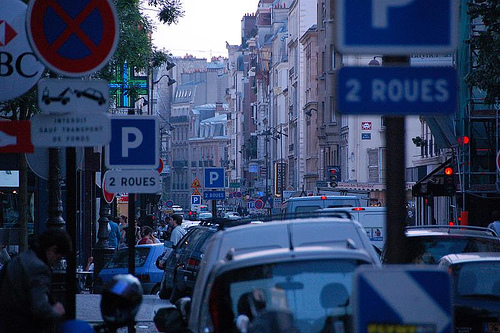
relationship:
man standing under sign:
[11, 227, 70, 332] [33, 112, 112, 143]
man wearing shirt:
[11, 227, 70, 332] [16, 253, 58, 319]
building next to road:
[286, 10, 305, 194] [155, 204, 499, 331]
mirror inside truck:
[210, 249, 371, 331] [274, 279, 303, 292]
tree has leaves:
[56, 1, 176, 296] [125, 19, 148, 70]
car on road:
[110, 245, 166, 298] [155, 204, 499, 331]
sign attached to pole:
[108, 117, 158, 166] [127, 107, 135, 329]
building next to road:
[244, 44, 281, 167] [155, 204, 499, 331]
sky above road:
[138, 3, 263, 55] [155, 204, 499, 331]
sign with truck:
[37, 79, 111, 113] [42, 84, 74, 108]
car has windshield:
[110, 245, 166, 298] [113, 248, 150, 267]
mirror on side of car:
[156, 306, 188, 331] [110, 245, 166, 298]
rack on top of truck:
[227, 242, 359, 252] [274, 279, 303, 292]